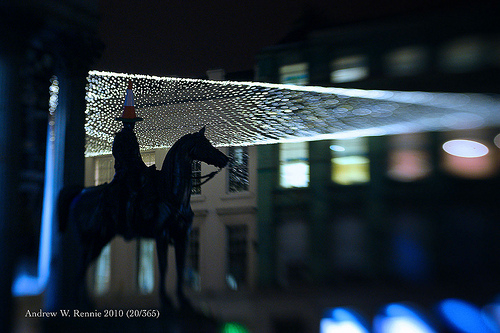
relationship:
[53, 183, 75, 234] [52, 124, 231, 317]
tail of horse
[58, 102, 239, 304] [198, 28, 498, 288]
statue in front of building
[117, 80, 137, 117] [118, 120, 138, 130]
traffic cone on head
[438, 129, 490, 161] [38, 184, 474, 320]
light going across street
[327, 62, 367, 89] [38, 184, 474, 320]
light going across street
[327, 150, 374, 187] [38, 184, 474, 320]
light going across street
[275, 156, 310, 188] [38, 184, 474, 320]
light going across street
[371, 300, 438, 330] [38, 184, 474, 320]
light going across street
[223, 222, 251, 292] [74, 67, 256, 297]
window in building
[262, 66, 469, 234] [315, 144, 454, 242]
lights on in building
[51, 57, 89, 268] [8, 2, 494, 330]
column on building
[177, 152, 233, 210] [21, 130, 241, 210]
reins on horse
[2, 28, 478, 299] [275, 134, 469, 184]
building with windows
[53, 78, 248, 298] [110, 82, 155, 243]
figure standing on man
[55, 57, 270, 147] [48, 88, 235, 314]
lights above statue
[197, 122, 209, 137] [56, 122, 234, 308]
ear of horse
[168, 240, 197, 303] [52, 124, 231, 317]
leg of horse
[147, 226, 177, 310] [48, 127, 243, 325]
leg of horse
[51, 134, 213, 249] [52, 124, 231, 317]
man on horse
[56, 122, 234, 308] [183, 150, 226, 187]
horse wearing bridal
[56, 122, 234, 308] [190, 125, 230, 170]
horse has a head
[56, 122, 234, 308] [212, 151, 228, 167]
horse has a mouth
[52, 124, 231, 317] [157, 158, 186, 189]
horse has a neck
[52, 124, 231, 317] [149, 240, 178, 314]
horse has a leg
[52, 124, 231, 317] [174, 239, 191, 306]
horse has a leg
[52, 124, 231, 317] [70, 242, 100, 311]
horse has a leg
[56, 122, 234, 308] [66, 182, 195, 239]
horse has a body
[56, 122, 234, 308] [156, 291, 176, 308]
horse has a foot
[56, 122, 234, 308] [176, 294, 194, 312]
horse has a foot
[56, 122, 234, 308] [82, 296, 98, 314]
horse has a foot